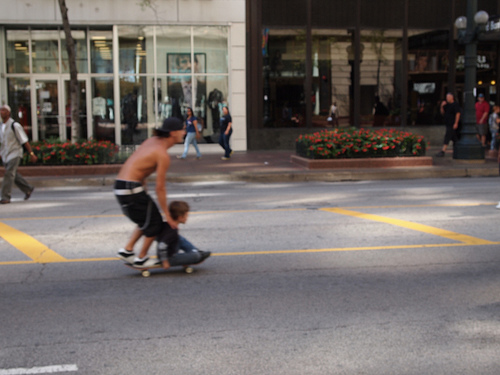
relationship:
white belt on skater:
[113, 185, 148, 199] [115, 103, 183, 257]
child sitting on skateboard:
[163, 200, 211, 263] [122, 261, 204, 280]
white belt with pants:
[113, 185, 148, 199] [112, 179, 175, 239]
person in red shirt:
[470, 94, 495, 150] [469, 100, 489, 126]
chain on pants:
[139, 190, 149, 235] [112, 179, 176, 256]